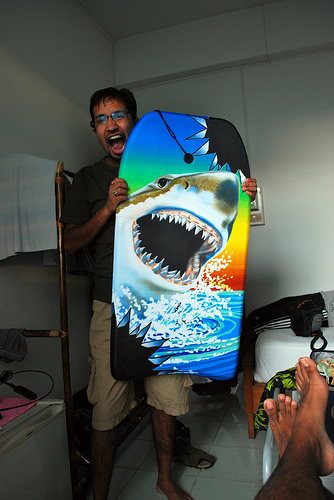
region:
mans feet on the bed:
[252, 354, 328, 498]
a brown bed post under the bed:
[238, 342, 266, 439]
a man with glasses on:
[87, 77, 139, 155]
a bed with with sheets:
[248, 318, 330, 377]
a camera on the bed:
[281, 287, 328, 344]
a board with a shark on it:
[106, 106, 253, 392]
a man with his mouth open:
[91, 79, 137, 159]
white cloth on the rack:
[4, 136, 85, 274]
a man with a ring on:
[104, 174, 125, 206]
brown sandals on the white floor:
[173, 408, 224, 491]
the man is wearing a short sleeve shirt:
[64, 152, 128, 301]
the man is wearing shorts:
[82, 295, 189, 425]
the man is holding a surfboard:
[59, 84, 249, 382]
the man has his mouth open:
[102, 130, 129, 154]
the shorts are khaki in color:
[82, 297, 194, 422]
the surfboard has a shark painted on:
[111, 109, 243, 379]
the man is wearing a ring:
[112, 190, 119, 196]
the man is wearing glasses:
[93, 110, 126, 124]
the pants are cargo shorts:
[84, 295, 196, 430]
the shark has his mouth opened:
[130, 201, 223, 294]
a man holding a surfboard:
[57, 85, 240, 497]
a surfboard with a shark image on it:
[107, 112, 252, 378]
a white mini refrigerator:
[0, 396, 74, 498]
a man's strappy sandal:
[172, 443, 215, 468]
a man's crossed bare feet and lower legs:
[254, 354, 332, 498]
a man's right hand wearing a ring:
[105, 176, 128, 211]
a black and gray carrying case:
[288, 291, 328, 352]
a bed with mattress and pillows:
[241, 288, 332, 440]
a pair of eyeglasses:
[88, 111, 128, 125]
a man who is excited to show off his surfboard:
[58, 85, 257, 498]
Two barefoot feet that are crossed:
[257, 365, 333, 469]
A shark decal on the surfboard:
[111, 174, 251, 308]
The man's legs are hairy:
[276, 436, 314, 498]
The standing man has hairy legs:
[91, 412, 187, 489]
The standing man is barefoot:
[156, 468, 185, 498]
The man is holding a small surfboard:
[95, 153, 272, 392]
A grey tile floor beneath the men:
[217, 425, 252, 490]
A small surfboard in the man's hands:
[114, 121, 249, 383]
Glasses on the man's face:
[92, 110, 131, 128]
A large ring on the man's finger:
[113, 189, 118, 200]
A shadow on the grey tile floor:
[195, 400, 257, 462]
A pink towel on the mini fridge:
[3, 395, 38, 424]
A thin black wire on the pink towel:
[0, 365, 54, 411]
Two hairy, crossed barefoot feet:
[255, 362, 332, 472]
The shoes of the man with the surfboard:
[173, 426, 214, 468]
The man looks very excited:
[93, 87, 142, 158]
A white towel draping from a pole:
[0, 152, 66, 256]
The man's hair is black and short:
[86, 82, 138, 113]